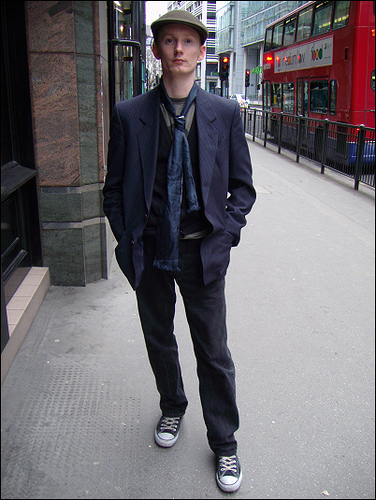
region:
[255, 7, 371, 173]
double decker bus on street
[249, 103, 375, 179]
fence on the sidewalk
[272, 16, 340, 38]
windows on top level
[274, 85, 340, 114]
windows on bottom level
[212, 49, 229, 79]
traffic light on street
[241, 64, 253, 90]
traffic light on street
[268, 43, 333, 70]
imaging and lettering on bus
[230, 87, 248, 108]
vehicle on roadside of street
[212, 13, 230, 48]
windows on a building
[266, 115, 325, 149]
wheels on the bus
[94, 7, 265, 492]
young man standing on sidewalk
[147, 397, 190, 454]
right foot and tennis shoe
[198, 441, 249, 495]
left foot and tennis shoe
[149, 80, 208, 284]
blue scarf around man's neck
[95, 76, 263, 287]
blue jacket not buttoned in front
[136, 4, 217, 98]
man's head and neck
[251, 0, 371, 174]
red double decker bus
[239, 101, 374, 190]
metal railing along sidewalk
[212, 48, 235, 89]
traffic light that is currently red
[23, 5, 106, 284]
stone blocks on wall of building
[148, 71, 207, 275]
Blue scarf around guy's neck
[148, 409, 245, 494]
A pair of black and white sneakers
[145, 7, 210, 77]
Hat on a guy's head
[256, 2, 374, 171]
A red double decker bus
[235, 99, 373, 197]
A long black iron fence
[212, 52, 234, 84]
A traffic light is lit red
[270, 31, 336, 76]
White sign on a bus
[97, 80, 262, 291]
The blazer is black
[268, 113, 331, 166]
Two tires on a bus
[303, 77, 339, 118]
A window on the bus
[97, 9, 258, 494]
Man posing for picture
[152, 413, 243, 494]
Man wearing black and white sneakers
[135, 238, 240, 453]
Man wearing black pants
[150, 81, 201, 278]
Man wearing blue scarf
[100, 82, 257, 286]
Man wearing a blue jacket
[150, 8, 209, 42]
Man wearing a green cap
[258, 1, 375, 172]
Doubledecker bus is red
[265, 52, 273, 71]
Red light on bus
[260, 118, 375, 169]
Bottom of bus is blue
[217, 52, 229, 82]
Traffic light is red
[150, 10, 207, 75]
man has on brown hat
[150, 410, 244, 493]
shoes are black and white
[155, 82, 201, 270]
scarf around neck is shiny and blue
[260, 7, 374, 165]
bus has two decks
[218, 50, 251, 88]
the traffic lights are red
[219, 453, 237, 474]
the shoe laces are white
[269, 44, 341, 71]
advertisement on the side of a bus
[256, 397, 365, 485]
the sidewalk is grey with white spots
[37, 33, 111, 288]
side of a building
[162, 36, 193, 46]
man has blue eyes